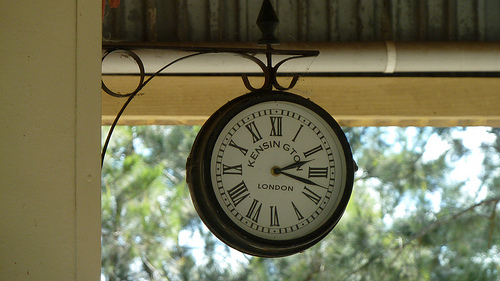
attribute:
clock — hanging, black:
[183, 90, 362, 260]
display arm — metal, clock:
[99, 42, 319, 173]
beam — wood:
[103, 74, 498, 119]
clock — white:
[185, 88, 354, 253]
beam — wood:
[100, 67, 499, 132]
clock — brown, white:
[153, 69, 402, 260]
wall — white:
[3, 1, 106, 279]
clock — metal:
[218, 96, 346, 253]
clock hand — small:
[278, 156, 314, 171]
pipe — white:
[91, 41, 499, 76]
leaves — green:
[116, 160, 159, 219]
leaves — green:
[102, 126, 494, 279]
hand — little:
[269, 151, 314, 176]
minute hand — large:
[273, 170, 316, 186]